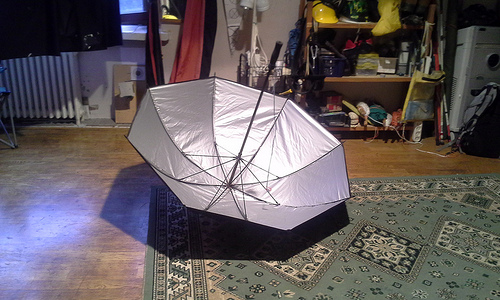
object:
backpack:
[453, 82, 500, 159]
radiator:
[4, 51, 81, 125]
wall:
[45, 9, 136, 115]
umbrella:
[125, 74, 352, 232]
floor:
[6, 122, 479, 298]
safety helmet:
[309, 2, 339, 25]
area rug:
[141, 173, 498, 299]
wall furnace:
[1, 52, 86, 118]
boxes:
[355, 50, 378, 78]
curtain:
[0, 0, 126, 59]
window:
[118, 0, 151, 41]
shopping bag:
[370, 2, 404, 36]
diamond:
[346, 222, 430, 281]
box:
[321, 90, 343, 111]